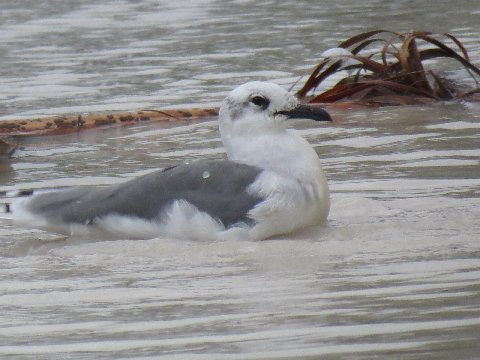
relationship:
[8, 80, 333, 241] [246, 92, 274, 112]
bird has eye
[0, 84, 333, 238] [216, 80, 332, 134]
bird has head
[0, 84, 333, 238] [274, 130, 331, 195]
bird has chest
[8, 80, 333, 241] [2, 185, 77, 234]
bird has feathers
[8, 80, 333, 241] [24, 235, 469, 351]
bird walking in water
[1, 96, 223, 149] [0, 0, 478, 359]
tree fallen down in water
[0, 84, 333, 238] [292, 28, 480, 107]
bird walking near plants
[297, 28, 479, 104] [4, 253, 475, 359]
plants floating in water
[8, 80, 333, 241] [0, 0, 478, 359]
bird floating in water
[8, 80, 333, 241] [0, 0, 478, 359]
bird in water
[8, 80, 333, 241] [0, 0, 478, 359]
bird on water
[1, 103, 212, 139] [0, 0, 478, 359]
tree in water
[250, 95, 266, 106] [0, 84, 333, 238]
eye belonging to bird